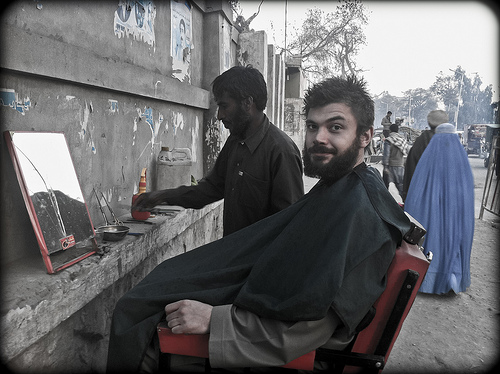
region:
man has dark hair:
[276, 69, 371, 187]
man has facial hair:
[290, 132, 356, 205]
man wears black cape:
[265, 195, 372, 330]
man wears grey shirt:
[186, 266, 345, 373]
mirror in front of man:
[22, 123, 97, 259]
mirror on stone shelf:
[4, 118, 102, 264]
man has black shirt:
[200, 132, 293, 237]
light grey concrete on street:
[417, 302, 495, 365]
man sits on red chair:
[150, 243, 435, 350]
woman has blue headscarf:
[418, 111, 479, 313]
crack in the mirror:
[8, 146, 65, 234]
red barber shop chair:
[157, 213, 430, 371]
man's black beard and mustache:
[301, 130, 361, 175]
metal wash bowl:
[97, 223, 128, 240]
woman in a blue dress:
[404, 121, 476, 292]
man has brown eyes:
[305, 121, 344, 133]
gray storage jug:
[157, 146, 193, 186]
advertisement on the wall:
[170, 2, 195, 82]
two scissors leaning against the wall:
[94, 189, 122, 229]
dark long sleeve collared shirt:
[142, 128, 302, 228]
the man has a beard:
[261, 80, 395, 182]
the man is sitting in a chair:
[196, 83, 492, 368]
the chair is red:
[138, 244, 462, 368]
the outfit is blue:
[416, 119, 468, 301]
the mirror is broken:
[0, 81, 145, 276]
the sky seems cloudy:
[388, 30, 480, 73]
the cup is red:
[114, 177, 168, 242]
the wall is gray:
[1, 291, 62, 339]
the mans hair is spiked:
[316, 83, 366, 113]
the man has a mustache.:
[283, 83, 398, 203]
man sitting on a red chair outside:
[155, 76, 424, 372]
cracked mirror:
[9, 128, 98, 275]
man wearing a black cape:
[108, 73, 405, 371]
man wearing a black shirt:
[136, 67, 300, 223]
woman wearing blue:
[410, 123, 472, 293]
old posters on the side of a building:
[110, 0, 192, 78]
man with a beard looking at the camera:
[298, 78, 368, 183]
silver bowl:
[96, 222, 132, 237]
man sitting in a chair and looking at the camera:
[287, 73, 386, 294]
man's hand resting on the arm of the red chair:
[164, 301, 216, 339]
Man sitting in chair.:
[151, 69, 443, 370]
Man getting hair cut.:
[152, 75, 443, 367]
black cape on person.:
[102, 155, 417, 369]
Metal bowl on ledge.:
[97, 220, 129, 240]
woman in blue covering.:
[404, 118, 474, 299]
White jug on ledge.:
[155, 136, 195, 201]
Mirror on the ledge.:
[5, 125, 105, 277]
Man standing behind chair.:
[134, 65, 313, 242]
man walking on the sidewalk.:
[379, 115, 411, 191]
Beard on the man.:
[297, 78, 378, 178]